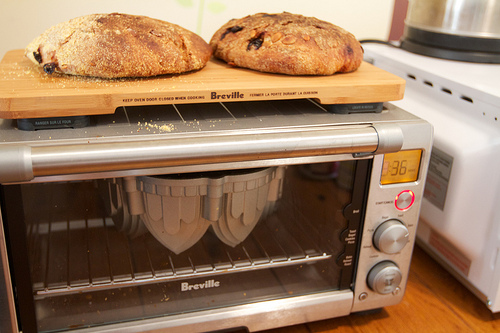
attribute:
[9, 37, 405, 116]
tray — wooden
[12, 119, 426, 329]
oven — toaster, Breville, silver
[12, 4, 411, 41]
wall — white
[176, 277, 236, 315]
logo — Breville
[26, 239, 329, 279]
grill — metal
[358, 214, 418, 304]
knobs — silver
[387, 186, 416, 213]
button — illuminated , silver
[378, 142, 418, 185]
window — display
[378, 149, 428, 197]
light — orange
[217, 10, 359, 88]
good — baked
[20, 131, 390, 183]
handle — silver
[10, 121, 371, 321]
door — oven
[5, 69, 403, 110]
board — wooden, cutting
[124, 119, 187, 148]
crumbs — small, brown, breads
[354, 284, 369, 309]
button — mini, silver